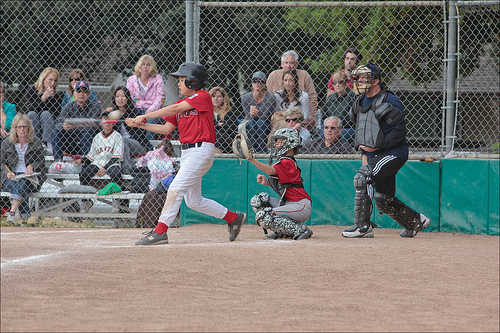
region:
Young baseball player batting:
[115, 60, 249, 253]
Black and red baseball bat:
[50, 115, 132, 132]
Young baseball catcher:
[228, 119, 325, 243]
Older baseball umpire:
[332, 54, 442, 248]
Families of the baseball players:
[13, 41, 388, 246]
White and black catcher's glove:
[230, 127, 253, 167]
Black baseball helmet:
[170, 57, 210, 92]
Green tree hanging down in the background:
[279, 2, 493, 77]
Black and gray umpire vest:
[348, 100, 390, 152]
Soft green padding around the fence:
[195, 155, 499, 230]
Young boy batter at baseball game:
[125, 57, 247, 247]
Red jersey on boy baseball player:
[163, 93, 216, 142]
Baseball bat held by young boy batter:
[63, 112, 130, 129]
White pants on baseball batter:
[155, 141, 231, 227]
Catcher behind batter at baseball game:
[232, 124, 315, 241]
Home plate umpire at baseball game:
[342, 64, 432, 241]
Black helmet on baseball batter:
[166, 59, 208, 91]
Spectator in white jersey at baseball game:
[79, 110, 126, 184]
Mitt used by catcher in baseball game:
[229, 132, 253, 162]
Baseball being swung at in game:
[101, 110, 126, 122]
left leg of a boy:
[163, 192, 177, 220]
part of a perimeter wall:
[218, 22, 273, 61]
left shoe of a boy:
[142, 236, 157, 241]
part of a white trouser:
[180, 162, 195, 182]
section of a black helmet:
[192, 65, 195, 73]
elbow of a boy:
[168, 105, 183, 115]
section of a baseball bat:
[107, 118, 114, 120]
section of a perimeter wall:
[420, 65, 425, 100]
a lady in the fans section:
[15, 126, 22, 157]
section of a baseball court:
[186, 256, 226, 266]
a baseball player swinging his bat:
[79, 44, 277, 248]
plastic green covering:
[429, 160, 490, 216]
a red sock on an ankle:
[154, 218, 174, 234]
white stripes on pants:
[376, 145, 389, 170]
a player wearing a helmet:
[249, 111, 316, 245]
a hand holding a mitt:
[234, 132, 257, 165]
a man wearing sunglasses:
[315, 107, 345, 156]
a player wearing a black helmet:
[147, 63, 226, 242]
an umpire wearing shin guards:
[343, 57, 423, 240]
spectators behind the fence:
[11, 60, 133, 208]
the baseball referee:
[341, 62, 425, 247]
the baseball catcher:
[237, 117, 323, 255]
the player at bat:
[129, 62, 246, 255]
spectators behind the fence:
[258, 59, 348, 146]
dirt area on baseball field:
[92, 275, 374, 321]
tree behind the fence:
[294, 5, 382, 52]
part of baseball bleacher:
[47, 191, 137, 218]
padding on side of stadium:
[437, 170, 499, 215]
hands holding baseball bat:
[64, 116, 152, 131]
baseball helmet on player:
[172, 61, 208, 93]